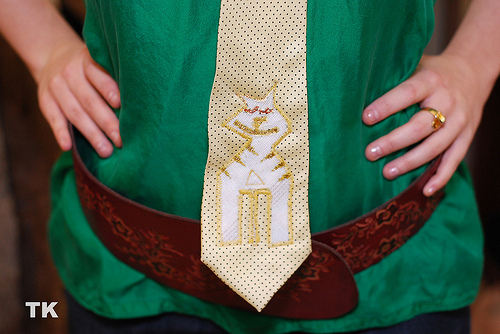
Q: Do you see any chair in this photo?
A: No, there are no chairs.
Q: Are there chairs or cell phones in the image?
A: No, there are no chairs or cell phones.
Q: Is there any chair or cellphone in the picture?
A: No, there are no chairs or cell phones.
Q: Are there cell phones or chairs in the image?
A: No, there are no chairs or cell phones.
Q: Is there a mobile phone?
A: No, there are no cell phones.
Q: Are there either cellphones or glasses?
A: No, there are no cellphones or glasses.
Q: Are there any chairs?
A: No, there are no chairs.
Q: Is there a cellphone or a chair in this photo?
A: No, there are no chairs or cell phones.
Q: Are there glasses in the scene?
A: No, there are no glasses.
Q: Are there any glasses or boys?
A: No, there are no glasses or boys.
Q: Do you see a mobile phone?
A: No, there are no cell phones.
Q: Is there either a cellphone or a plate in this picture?
A: No, there are no cell phones or plates.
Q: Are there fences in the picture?
A: No, there are no fences.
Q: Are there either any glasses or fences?
A: No, there are no fences or glasses.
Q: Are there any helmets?
A: No, there are no helmets.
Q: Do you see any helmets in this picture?
A: No, there are no helmets.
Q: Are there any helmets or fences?
A: No, there are no helmets or fences.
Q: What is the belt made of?
A: The belt is made of leather.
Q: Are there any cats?
A: Yes, there is a cat.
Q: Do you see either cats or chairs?
A: Yes, there is a cat.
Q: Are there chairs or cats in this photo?
A: Yes, there is a cat.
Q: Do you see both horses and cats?
A: No, there is a cat but no horses.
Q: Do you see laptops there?
A: No, there are no laptops.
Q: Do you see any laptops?
A: No, there are no laptops.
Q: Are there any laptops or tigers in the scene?
A: No, there are no laptops or tigers.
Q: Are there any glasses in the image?
A: No, there are no glasses.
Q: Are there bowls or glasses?
A: No, there are no glasses or bowls.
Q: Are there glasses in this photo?
A: No, there are no glasses.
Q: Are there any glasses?
A: No, there are no glasses.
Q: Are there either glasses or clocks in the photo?
A: No, there are no glasses or clocks.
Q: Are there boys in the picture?
A: No, there are no boys.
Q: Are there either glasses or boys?
A: No, there are no boys or glasses.